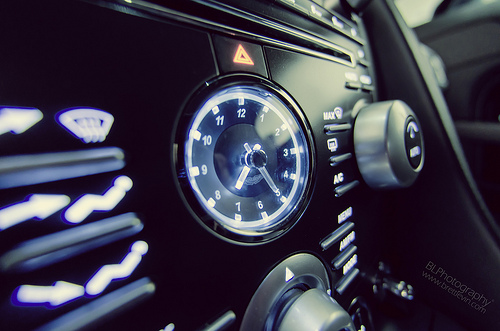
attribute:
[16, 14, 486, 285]
truck — black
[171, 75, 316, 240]
clock — lit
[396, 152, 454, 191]
ground — clean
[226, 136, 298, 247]
7:25 —  The time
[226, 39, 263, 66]
sign — triangular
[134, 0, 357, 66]
cd slot —  for  CD  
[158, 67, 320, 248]
clock — small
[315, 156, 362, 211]
ac —  the writing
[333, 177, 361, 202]
indicator —  for  air conditioning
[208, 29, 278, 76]
button —  for caution light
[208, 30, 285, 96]
light — lit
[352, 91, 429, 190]
wheel — small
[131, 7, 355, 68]
cd player — for cd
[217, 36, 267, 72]
triangle — orange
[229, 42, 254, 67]
symbol — reddish orange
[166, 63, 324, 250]
clock face — illuminated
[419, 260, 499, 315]
information — photographer's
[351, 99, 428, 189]
knob — big,  for   control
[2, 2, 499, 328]
dashboard —  vehicle's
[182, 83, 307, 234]
speedometer — lit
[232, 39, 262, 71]
triangle — orange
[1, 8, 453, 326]
lights — on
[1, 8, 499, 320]
truck dash — black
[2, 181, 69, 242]
arrow — lit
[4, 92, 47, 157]
arrow — lit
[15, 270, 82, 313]
arrow — lit